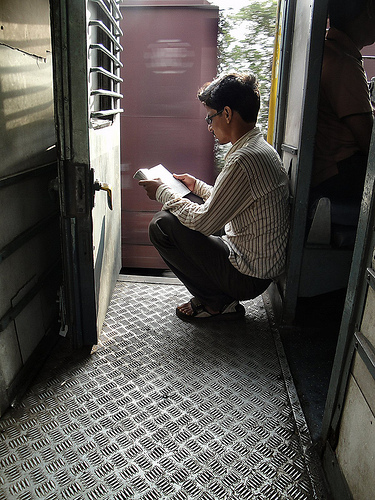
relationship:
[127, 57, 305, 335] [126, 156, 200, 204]
man holds book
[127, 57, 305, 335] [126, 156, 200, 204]
man reading book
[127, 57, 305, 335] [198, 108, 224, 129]
man wears eyeglasses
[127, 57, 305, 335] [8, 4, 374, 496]
man on train car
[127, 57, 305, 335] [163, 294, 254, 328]
man wears sandals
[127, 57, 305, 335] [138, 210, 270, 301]
man wears dark pants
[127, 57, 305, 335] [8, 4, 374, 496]
man in vehicle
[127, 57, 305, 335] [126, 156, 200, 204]
man reads book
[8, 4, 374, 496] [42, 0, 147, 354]
vehicle has door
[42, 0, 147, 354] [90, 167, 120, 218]
door has handle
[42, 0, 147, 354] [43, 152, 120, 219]
door has lock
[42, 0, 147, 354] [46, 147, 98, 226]
door has latch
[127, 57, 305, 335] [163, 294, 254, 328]
man wears sandal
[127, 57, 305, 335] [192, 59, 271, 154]
man has head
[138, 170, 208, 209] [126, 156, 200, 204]
hands holding book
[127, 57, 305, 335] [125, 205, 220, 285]
man sit knees bent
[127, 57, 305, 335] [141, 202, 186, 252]
person left knee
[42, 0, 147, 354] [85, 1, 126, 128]
door has window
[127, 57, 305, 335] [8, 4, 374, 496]
man takes train ride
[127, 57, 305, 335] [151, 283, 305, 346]
man with no seat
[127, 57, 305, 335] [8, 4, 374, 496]
man travel on train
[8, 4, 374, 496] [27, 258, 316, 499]
train no seats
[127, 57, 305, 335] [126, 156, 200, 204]
man concentrating on book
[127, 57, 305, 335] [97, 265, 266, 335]
man sits in door step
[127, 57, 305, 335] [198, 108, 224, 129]
man wears eyeglass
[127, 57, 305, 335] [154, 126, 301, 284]
man wear shirt